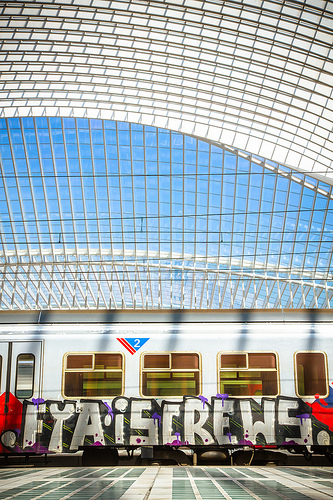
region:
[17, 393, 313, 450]
Graffiti on the side of the train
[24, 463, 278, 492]
The floor of the train terminal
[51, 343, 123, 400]
A window of the train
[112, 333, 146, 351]
A number on the train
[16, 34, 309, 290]
The top of the train terminal building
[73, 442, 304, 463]
The bottom of the train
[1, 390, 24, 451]
The color of the graffiti is red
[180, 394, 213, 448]
The letter "R" in the words of the graffiti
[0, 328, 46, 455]
The door to the train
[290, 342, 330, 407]
The back window to the train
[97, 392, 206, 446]
graffiti on the train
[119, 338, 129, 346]
two red stripes on the train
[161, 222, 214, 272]
glass roof at the train station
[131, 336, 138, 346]
2 written is white on the train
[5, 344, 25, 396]
doors on the train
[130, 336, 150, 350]
blue triangle on the train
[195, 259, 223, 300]
white metal beams in the roof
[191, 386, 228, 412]
purple paint looks like it was dripping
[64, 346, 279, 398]
three windows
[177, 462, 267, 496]
green stripes on the ground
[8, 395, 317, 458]
writing on a train.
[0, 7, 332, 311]
a giant cage over a train.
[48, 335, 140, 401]
a window on a train.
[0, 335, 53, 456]
a door on a train.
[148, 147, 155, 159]
a section of a blue sky.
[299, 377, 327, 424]
red spray paint.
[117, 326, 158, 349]
a number 2 on blue paint.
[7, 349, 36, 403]
a window on a door.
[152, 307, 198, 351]
a shadow cast on a train.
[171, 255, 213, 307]
metal scaffolding.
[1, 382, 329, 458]
graffiti on the train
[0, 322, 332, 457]
a white train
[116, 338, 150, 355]
a triangle on the train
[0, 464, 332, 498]
a tiled floor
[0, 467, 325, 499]
green tiles on the floor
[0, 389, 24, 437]
red on the train doors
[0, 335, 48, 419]
the train doors are closed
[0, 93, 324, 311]
blue sky through the window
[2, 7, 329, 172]
the roof is white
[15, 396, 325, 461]
purple spots on the graffiti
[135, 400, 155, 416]
part of a train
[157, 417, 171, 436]
side of a train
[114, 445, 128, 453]
part of a rail way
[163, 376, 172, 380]
part of a window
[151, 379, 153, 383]
edge of a window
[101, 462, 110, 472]
part of a train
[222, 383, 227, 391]
edge of a window